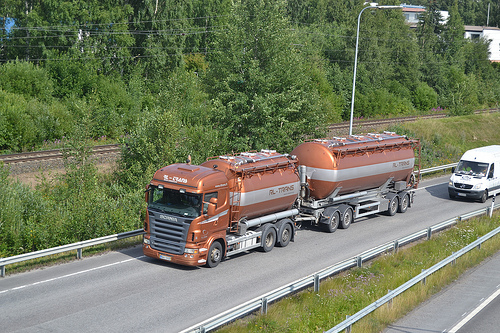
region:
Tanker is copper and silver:
[296, 138, 431, 181]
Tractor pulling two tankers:
[109, 127, 444, 270]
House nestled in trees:
[391, 0, 446, 27]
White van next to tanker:
[432, 131, 499, 202]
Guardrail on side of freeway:
[1, 239, 108, 266]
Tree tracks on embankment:
[6, 137, 106, 181]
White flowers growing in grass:
[331, 210, 496, 301]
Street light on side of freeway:
[336, 2, 396, 131]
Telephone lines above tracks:
[5, 15, 207, 57]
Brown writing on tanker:
[262, 178, 302, 200]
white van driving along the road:
[443, 142, 498, 207]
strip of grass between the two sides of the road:
[227, 208, 497, 332]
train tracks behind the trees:
[3, 138, 121, 168]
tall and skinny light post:
[344, 3, 379, 146]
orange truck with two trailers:
[121, 126, 431, 273]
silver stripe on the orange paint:
[226, 178, 303, 211]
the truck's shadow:
[107, 228, 147, 259]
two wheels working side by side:
[254, 218, 299, 252]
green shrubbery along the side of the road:
[3, 170, 149, 257]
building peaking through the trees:
[402, 6, 499, 72]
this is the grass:
[313, 288, 345, 309]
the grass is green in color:
[291, 296, 339, 328]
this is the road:
[48, 286, 127, 309]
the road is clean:
[60, 280, 118, 305]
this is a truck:
[136, 129, 422, 267]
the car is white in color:
[476, 148, 494, 157]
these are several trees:
[4, 28, 491, 92]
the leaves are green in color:
[106, 55, 213, 89]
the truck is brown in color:
[173, 165, 199, 176]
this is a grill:
[302, 275, 321, 289]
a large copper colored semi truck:
[143, 133, 417, 268]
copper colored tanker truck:
[142, 159, 299, 269]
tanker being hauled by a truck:
[295, 132, 417, 232]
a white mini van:
[447, 141, 499, 199]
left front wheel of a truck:
[205, 239, 227, 266]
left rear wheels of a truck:
[261, 221, 294, 248]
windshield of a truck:
[143, 183, 200, 214]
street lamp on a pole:
[349, 3, 429, 130]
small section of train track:
[2, 145, 127, 165]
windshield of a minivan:
[453, 156, 493, 178]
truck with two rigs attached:
[141, 127, 422, 267]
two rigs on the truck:
[227, 128, 419, 253]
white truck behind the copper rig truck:
[447, 143, 499, 203]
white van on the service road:
[446, 142, 498, 202]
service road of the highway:
[2, 269, 499, 331]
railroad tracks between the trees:
[2, 142, 119, 159]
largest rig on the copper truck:
[300, 129, 418, 233]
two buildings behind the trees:
[377, 2, 498, 64]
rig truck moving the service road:
[137, 130, 424, 269]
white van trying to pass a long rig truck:
[448, 143, 498, 200]